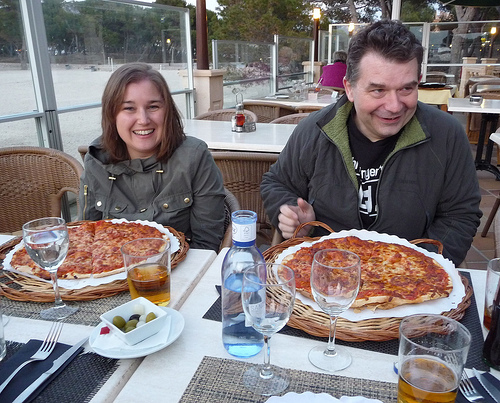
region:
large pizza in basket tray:
[298, 221, 447, 301]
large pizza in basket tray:
[41, 217, 165, 267]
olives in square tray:
[101, 301, 156, 334]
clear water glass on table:
[228, 262, 287, 392]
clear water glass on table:
[308, 250, 363, 372]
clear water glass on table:
[29, 229, 71, 304]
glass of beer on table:
[392, 317, 461, 396]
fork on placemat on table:
[37, 311, 55, 360]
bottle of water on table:
[217, 210, 262, 359]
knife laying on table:
[59, 329, 86, 376]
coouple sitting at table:
[77, 13, 474, 284]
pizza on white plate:
[287, 228, 460, 323]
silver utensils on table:
[19, 319, 88, 396]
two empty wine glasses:
[237, 248, 360, 369]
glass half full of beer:
[116, 235, 184, 315]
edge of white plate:
[343, 222, 391, 242]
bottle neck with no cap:
[217, 199, 278, 265]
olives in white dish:
[105, 294, 171, 345]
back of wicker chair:
[9, 147, 54, 203]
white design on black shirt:
[350, 157, 390, 222]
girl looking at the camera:
[75, 41, 219, 193]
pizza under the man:
[293, 233, 445, 318]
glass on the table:
[381, 326, 466, 398]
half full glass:
[378, 309, 490, 400]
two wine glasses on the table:
[218, 247, 376, 358]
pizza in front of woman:
[51, 218, 139, 282]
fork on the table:
[31, 318, 71, 358]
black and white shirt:
[346, 138, 386, 213]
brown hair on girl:
[80, 53, 190, 154]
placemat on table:
[166, 346, 231, 401]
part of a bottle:
[225, 287, 242, 323]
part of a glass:
[381, 331, 426, 389]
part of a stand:
[309, 292, 342, 346]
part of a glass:
[256, 297, 272, 333]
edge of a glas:
[256, 280, 283, 304]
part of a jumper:
[381, 161, 420, 215]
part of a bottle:
[219, 327, 255, 360]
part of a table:
[144, 343, 173, 376]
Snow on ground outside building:
[56, 53, 107, 116]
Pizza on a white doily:
[291, 225, 456, 313]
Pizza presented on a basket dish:
[270, 235, 460, 340]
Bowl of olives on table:
[88, 298, 189, 365]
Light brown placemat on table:
[179, 355, 319, 401]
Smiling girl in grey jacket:
[71, 80, 212, 217]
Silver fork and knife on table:
[16, 319, 86, 400]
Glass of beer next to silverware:
[398, 320, 499, 401]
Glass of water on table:
[26, 215, 84, 322]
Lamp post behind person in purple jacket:
[298, 4, 343, 89]